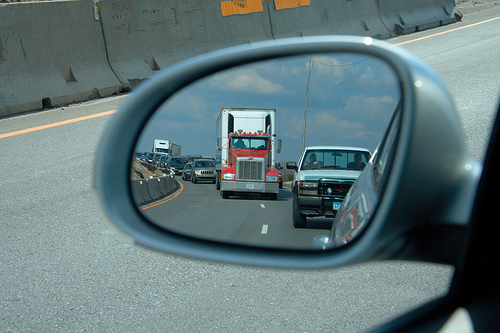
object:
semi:
[211, 105, 291, 198]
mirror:
[93, 34, 467, 270]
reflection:
[128, 52, 402, 251]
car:
[290, 144, 373, 227]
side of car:
[418, 65, 481, 217]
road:
[156, 163, 359, 249]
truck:
[153, 139, 182, 156]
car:
[151, 153, 159, 164]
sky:
[280, 52, 399, 126]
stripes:
[260, 224, 268, 234]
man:
[305, 153, 324, 166]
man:
[347, 153, 367, 169]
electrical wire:
[314, 57, 374, 67]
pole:
[301, 52, 313, 152]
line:
[260, 204, 267, 209]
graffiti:
[110, 8, 190, 37]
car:
[138, 151, 148, 160]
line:
[0, 98, 130, 148]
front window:
[233, 138, 268, 151]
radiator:
[322, 198, 347, 214]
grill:
[236, 159, 265, 182]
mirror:
[285, 161, 296, 169]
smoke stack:
[221, 108, 275, 133]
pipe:
[229, 132, 269, 137]